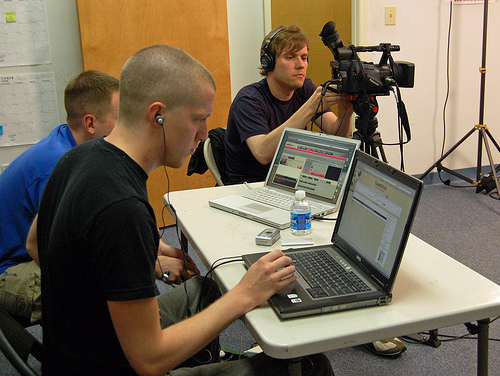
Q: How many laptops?
A: 2.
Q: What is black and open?
A: Laptop.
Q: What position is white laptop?
A: Open.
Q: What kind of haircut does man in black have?
A: Close.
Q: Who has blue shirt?
A: Man in back.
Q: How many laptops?
A: 2.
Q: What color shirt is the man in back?
A: Blue.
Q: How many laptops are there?
A: 2.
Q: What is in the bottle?
A: Water.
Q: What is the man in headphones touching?
A: Camera.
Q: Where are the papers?
A: Wall.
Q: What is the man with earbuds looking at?
A: Laptop.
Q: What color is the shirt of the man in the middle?
A: Blue.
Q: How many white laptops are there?
A: 1.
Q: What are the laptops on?
A: Table.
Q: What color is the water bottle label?
A: Blue.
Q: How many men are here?
A: Three.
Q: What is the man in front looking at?
A: Laptop.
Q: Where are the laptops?
A: On the table.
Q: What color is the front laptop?
A: Black.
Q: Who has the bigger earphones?
A: The man in the back.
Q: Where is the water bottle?
A: On the table.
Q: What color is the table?
A: White.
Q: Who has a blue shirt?
A: The man in the middle.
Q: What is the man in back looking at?
A: A camera.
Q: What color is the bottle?
A: Blue.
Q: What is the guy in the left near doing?
A: Listening to headphones.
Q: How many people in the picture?
A: Three.